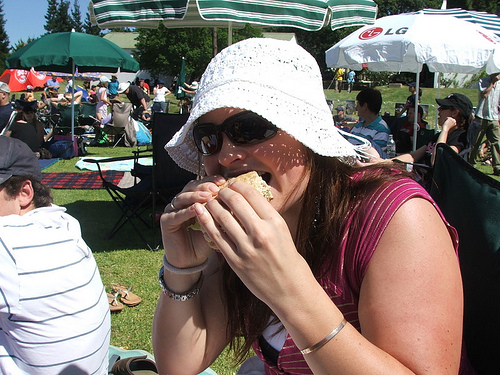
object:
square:
[173, 294, 180, 303]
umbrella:
[2, 28, 141, 162]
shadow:
[48, 183, 189, 253]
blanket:
[38, 169, 125, 191]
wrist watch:
[155, 267, 206, 302]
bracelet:
[295, 318, 348, 356]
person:
[332, 67, 348, 94]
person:
[344, 66, 355, 94]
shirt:
[344, 70, 358, 85]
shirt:
[331, 67, 344, 84]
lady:
[147, 36, 464, 374]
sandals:
[103, 291, 124, 314]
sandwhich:
[186, 170, 273, 255]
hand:
[191, 176, 314, 307]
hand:
[157, 168, 227, 270]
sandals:
[106, 281, 141, 306]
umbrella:
[323, 10, 499, 151]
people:
[343, 88, 391, 159]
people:
[386, 104, 428, 148]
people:
[353, 91, 475, 171]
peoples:
[464, 71, 499, 177]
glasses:
[186, 109, 278, 159]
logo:
[355, 26, 410, 41]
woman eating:
[170, 169, 290, 244]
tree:
[40, 1, 102, 38]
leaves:
[60, 16, 70, 28]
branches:
[46, 12, 60, 23]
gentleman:
[0, 136, 109, 374]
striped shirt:
[0, 204, 113, 374]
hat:
[162, 35, 365, 178]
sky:
[0, 0, 136, 56]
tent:
[83, 0, 380, 44]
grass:
[0, 76, 499, 374]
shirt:
[233, 165, 462, 374]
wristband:
[159, 251, 209, 276]